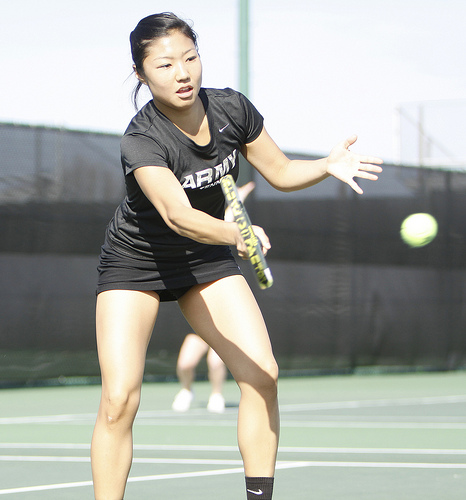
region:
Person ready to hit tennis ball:
[76, 6, 441, 497]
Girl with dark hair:
[119, 8, 219, 113]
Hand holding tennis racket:
[213, 162, 287, 293]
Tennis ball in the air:
[385, 199, 442, 257]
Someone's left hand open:
[319, 126, 384, 197]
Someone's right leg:
[79, 313, 156, 496]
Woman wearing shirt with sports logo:
[80, 2, 272, 146]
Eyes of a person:
[147, 46, 197, 73]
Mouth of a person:
[170, 81, 198, 102]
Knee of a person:
[223, 354, 291, 411]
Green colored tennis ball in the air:
[378, 207, 451, 252]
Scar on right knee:
[97, 404, 119, 424]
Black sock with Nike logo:
[238, 468, 276, 499]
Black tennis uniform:
[90, 87, 283, 316]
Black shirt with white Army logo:
[167, 151, 239, 193]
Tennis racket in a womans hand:
[205, 172, 274, 288]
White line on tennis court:
[289, 451, 403, 469]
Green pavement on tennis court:
[302, 429, 362, 444]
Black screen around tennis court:
[288, 235, 398, 342]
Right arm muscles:
[131, 166, 234, 259]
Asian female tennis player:
[58, 2, 388, 499]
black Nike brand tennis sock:
[234, 462, 280, 498]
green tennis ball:
[390, 189, 444, 274]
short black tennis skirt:
[101, 194, 244, 311]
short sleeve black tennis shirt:
[107, 79, 256, 257]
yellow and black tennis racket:
[215, 159, 274, 297]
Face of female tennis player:
[105, 6, 231, 133]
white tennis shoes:
[159, 371, 224, 426]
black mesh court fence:
[295, 204, 403, 368]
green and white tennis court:
[294, 379, 463, 498]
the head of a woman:
[124, 5, 213, 115]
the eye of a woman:
[153, 59, 174, 70]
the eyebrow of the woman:
[150, 52, 176, 63]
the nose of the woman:
[174, 60, 192, 82]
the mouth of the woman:
[172, 80, 197, 99]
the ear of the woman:
[129, 61, 148, 86]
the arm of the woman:
[122, 135, 236, 254]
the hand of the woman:
[320, 131, 386, 200]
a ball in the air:
[397, 203, 439, 254]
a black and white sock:
[241, 471, 280, 498]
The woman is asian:
[123, 24, 269, 257]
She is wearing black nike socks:
[241, 461, 277, 498]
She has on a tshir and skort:
[107, 105, 328, 329]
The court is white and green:
[302, 403, 344, 482]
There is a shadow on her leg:
[179, 283, 298, 426]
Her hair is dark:
[131, 1, 224, 126]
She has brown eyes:
[157, 54, 203, 73]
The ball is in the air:
[376, 181, 460, 258]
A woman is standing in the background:
[169, 313, 264, 430]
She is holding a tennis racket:
[133, 143, 316, 307]